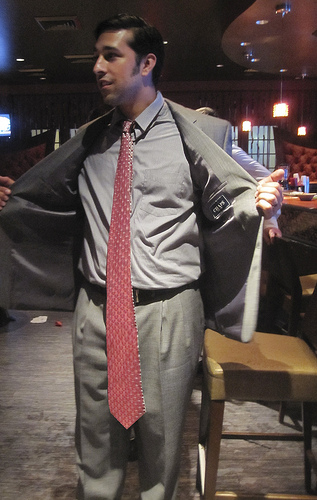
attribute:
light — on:
[294, 110, 310, 139]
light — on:
[269, 77, 293, 123]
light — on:
[235, 99, 251, 134]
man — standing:
[56, 15, 219, 499]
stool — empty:
[195, 322, 316, 499]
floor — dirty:
[2, 308, 316, 499]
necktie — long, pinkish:
[104, 117, 153, 431]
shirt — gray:
[65, 92, 205, 297]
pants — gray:
[66, 280, 206, 499]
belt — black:
[80, 272, 203, 304]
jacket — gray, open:
[2, 93, 276, 344]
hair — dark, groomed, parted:
[91, 10, 166, 91]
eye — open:
[104, 51, 122, 63]